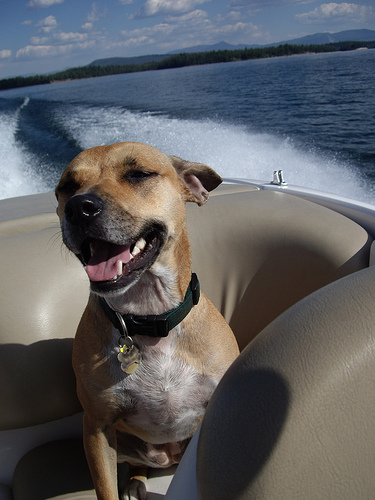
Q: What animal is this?
A: A dog.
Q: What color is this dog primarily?
A: Brown.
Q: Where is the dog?
A: On a boat.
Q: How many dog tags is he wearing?
A: 2.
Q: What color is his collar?
A: Black.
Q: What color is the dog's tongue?
A: Pink.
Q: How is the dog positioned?
A: Sitting.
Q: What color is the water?
A: Blue.